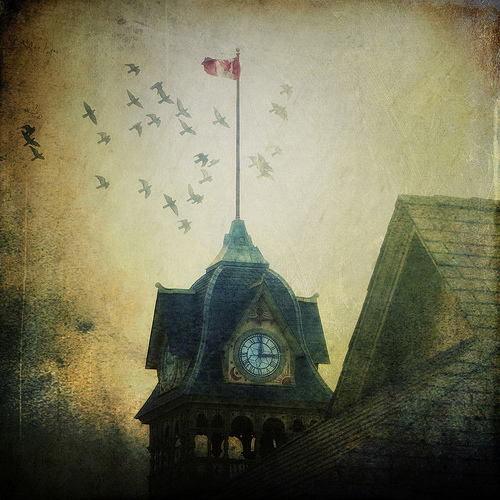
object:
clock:
[233, 326, 287, 383]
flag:
[200, 56, 240, 82]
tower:
[133, 45, 334, 497]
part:
[0, 2, 500, 234]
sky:
[0, 1, 499, 450]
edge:
[242, 328, 284, 343]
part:
[133, 218, 337, 429]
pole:
[235, 48, 241, 220]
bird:
[161, 192, 179, 217]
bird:
[93, 174, 111, 191]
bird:
[28, 145, 46, 162]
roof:
[205, 219, 269, 272]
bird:
[81, 101, 98, 126]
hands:
[257, 338, 264, 355]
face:
[238, 334, 282, 378]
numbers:
[241, 355, 257, 370]